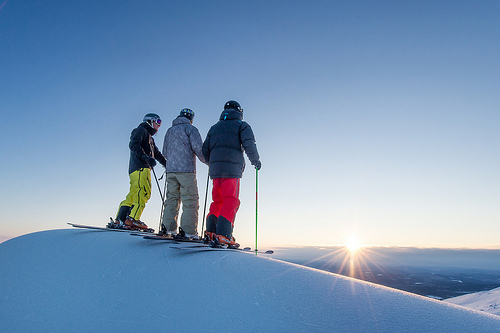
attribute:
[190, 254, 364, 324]
snow — white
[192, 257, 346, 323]
snow — white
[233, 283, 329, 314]
snow — white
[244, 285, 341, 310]
snow — white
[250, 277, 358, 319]
snow — white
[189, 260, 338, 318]
snow — white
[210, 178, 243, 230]
pants — red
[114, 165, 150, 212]
pants — yellow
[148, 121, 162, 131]
eyes — man's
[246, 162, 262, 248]
pole — ski, green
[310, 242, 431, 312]
hill — snowy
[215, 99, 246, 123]
head — man's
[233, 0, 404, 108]
sky — blue, cloudless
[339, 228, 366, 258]
sun — bright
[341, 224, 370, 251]
sun — bright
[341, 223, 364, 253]
sun — bright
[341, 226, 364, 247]
sun — bright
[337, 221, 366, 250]
sun — bright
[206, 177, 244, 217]
pants — red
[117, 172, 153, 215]
pants — yellow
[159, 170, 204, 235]
pants — tan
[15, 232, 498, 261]
line — horizon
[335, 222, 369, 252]
sun — shining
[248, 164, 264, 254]
pole — bright